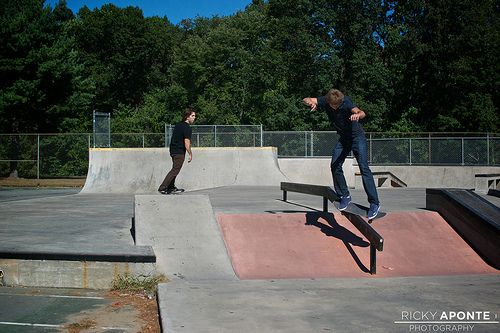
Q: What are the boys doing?
A: Skateboarding.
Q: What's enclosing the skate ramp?
A: Fence.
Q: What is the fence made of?
A: Metal.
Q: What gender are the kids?
A: Male.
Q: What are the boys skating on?
A: Ramps.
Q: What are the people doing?
A: Skateboarding.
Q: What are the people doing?
A: Skateboarding.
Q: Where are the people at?
A: Skatepark.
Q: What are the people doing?
A: Skateboarding.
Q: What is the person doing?
A: A trick.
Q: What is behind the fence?
A: Thick trees.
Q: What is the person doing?
A: Skateboarding on railing.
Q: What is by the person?
A: Shadow.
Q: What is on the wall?
A: Fence.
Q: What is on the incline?
A: Faded red paint.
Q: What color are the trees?
A: Green.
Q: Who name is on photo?
A: Ricky aponte.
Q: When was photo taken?
A: During the day.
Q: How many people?
A: Two.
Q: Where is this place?
A: Ramp park.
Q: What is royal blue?
A: Shoes.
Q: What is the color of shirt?
A: Black.